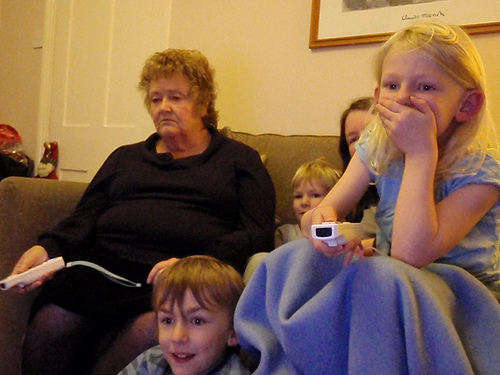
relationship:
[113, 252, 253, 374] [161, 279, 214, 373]
boy has a face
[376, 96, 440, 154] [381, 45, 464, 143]
hand on her face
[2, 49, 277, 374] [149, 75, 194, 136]
woman has a face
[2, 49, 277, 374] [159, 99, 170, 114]
woman has a nose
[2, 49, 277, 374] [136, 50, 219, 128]
woman has curly hair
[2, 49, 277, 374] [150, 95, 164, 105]
woman has a right eye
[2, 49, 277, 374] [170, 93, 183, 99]
woman has a left eye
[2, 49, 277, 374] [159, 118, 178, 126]
woman has a mouth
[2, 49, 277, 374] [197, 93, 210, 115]
woman has an ear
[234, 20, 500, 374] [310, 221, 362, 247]
girl holding wiimote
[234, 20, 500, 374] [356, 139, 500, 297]
girl wearing a dress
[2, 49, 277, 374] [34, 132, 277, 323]
woman in black clothes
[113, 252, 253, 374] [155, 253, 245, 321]
boy with brown hair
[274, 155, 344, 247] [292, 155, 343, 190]
boy with blonde hair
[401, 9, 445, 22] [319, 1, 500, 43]
signature on picture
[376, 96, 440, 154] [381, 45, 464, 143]
hand on face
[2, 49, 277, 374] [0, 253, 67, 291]
woman holds wiimote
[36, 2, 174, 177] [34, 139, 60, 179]
door with a puppet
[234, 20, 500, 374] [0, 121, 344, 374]
girl on a couch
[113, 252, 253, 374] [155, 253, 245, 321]
boy has brown hair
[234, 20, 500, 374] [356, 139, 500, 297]
girl in blue dress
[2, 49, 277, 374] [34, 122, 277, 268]
woman in black sweater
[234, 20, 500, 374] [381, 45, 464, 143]
girl with hand to her face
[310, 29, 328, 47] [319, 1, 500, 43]
corner of picture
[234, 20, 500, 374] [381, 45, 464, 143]
girl covering face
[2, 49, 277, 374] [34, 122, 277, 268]
woman has dark sweater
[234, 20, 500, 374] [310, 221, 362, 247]
girl with a wiimote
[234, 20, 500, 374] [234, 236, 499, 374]
girl with a blanket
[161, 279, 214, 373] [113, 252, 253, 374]
face of boy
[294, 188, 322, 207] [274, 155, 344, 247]
face of boy